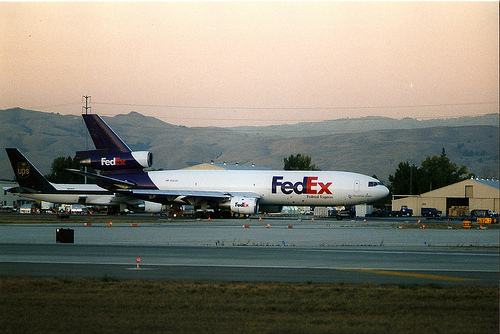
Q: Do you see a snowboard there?
A: No, there are no snowboards.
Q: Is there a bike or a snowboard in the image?
A: No, there are no snowboards or bikes.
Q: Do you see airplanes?
A: Yes, there is an airplane.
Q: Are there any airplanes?
A: Yes, there is an airplane.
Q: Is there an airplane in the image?
A: Yes, there is an airplane.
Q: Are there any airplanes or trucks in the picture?
A: Yes, there is an airplane.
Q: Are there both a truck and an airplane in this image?
A: Yes, there are both an airplane and a truck.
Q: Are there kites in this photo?
A: No, there are no kites.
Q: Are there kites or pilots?
A: No, there are no kites or pilots.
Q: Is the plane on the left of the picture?
A: Yes, the plane is on the left of the image.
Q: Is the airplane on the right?
A: No, the airplane is on the left of the image.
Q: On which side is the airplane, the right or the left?
A: The airplane is on the left of the image.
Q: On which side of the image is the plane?
A: The plane is on the left of the image.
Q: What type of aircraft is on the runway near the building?
A: The aircraft is an airplane.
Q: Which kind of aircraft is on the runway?
A: The aircraft is an airplane.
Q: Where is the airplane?
A: The airplane is on the runway.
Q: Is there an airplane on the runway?
A: Yes, there is an airplane on the runway.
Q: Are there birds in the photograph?
A: No, there are no birds.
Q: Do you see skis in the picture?
A: No, there are no skis.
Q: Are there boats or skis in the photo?
A: No, there are no skis or boats.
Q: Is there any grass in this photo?
A: Yes, there is grass.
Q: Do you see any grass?
A: Yes, there is grass.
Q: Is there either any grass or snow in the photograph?
A: Yes, there is grass.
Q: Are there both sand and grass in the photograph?
A: No, there is grass but no sand.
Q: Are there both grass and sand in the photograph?
A: No, there is grass but no sand.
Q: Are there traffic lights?
A: No, there are no traffic lights.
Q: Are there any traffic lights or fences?
A: No, there are no traffic lights or fences.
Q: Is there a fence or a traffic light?
A: No, there are no traffic lights or fences.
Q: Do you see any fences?
A: No, there are no fences.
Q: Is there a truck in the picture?
A: Yes, there is a truck.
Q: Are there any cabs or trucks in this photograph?
A: Yes, there is a truck.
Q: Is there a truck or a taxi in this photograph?
A: Yes, there is a truck.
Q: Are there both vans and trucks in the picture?
A: No, there is a truck but no vans.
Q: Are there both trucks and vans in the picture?
A: No, there is a truck but no vans.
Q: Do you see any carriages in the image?
A: No, there are no carriages.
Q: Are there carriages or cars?
A: No, there are no carriages or cars.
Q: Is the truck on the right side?
A: Yes, the truck is on the right of the image.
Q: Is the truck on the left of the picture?
A: No, the truck is on the right of the image.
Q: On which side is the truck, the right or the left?
A: The truck is on the right of the image.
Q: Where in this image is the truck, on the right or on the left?
A: The truck is on the right of the image.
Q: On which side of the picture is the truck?
A: The truck is on the right of the image.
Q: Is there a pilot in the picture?
A: No, there are no pilots.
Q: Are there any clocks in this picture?
A: No, there are no clocks.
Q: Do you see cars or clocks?
A: No, there are no clocks or cars.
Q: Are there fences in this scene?
A: No, there are no fences.